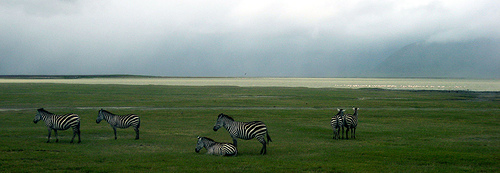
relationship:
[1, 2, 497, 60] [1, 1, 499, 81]
clouds in sky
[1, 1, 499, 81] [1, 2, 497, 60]
blue sky has white clouds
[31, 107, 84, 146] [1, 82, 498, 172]
zebra in grassy area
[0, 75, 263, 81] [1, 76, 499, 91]
land on other side of water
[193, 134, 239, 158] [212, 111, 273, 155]
zebra laying under standing zebra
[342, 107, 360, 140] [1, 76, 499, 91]
zebra looking toward water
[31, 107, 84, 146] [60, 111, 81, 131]
zebra has stripes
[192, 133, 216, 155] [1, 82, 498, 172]
head resting on grass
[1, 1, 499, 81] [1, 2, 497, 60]
sky with clouds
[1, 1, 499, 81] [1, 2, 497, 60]
sky has clouds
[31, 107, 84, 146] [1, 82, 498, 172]
zebra on top of grass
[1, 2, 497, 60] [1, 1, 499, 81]
clouds are in sky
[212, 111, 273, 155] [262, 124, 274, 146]
zebra has tail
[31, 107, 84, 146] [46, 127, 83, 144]
zebra has leg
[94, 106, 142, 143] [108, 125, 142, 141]
zebra has leg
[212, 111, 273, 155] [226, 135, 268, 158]
zebra has leg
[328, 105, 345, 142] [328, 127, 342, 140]
zebra has leg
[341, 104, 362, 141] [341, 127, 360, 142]
zebra has leg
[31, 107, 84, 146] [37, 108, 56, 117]
zebra has hair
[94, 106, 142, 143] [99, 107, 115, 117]
zebra has hair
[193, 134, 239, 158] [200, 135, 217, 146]
zebra has hair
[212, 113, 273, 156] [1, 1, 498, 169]
standing zebra in photo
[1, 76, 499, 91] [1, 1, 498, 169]
water in photo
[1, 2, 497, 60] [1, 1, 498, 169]
clouds in photo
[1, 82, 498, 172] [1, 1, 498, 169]
grass in photo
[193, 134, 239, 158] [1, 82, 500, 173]
zebra laying on grassy area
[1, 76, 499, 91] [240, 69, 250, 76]
lake has birds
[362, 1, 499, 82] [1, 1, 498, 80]
hills in background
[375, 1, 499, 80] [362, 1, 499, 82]
trees on top of hill